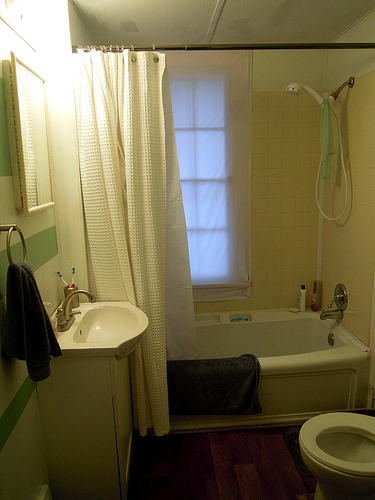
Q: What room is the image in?
A: It is at the bathroom.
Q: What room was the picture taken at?
A: It was taken at the bathroom.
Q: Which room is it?
A: It is a bathroom.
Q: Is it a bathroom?
A: Yes, it is a bathroom.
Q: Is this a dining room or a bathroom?
A: It is a bathroom.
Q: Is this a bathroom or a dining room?
A: It is a bathroom.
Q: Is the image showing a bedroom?
A: No, the picture is showing a bathroom.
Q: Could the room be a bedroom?
A: No, it is a bathroom.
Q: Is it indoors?
A: Yes, it is indoors.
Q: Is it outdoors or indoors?
A: It is indoors.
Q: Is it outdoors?
A: No, it is indoors.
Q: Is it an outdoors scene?
A: No, it is indoors.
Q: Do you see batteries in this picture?
A: No, there are no batteries.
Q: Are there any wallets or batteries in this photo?
A: No, there are no batteries or wallets.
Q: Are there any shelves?
A: No, there are no shelves.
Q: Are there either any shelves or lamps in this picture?
A: No, there are no shelves or lamps.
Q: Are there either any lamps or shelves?
A: No, there are no shelves or lamps.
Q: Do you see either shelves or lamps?
A: No, there are no shelves or lamps.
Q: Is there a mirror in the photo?
A: Yes, there is a mirror.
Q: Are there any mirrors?
A: Yes, there is a mirror.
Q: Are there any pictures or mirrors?
A: Yes, there is a mirror.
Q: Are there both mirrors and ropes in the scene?
A: No, there is a mirror but no ropes.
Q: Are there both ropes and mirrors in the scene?
A: No, there is a mirror but no ropes.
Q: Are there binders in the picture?
A: No, there are no binders.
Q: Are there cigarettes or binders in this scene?
A: No, there are no binders or cigarettes.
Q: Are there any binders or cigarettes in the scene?
A: No, there are no binders or cigarettes.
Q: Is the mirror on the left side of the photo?
A: Yes, the mirror is on the left of the image.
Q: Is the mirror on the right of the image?
A: No, the mirror is on the left of the image.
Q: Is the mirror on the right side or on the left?
A: The mirror is on the left of the image.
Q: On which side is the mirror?
A: The mirror is on the left of the image.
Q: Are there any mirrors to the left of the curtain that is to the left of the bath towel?
A: Yes, there is a mirror to the left of the curtain.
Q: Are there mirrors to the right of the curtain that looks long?
A: No, the mirror is to the left of the curtain.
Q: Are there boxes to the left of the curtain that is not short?
A: No, there is a mirror to the left of the curtain.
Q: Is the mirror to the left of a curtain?
A: Yes, the mirror is to the left of a curtain.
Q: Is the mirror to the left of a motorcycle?
A: No, the mirror is to the left of a curtain.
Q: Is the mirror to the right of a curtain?
A: No, the mirror is to the left of a curtain.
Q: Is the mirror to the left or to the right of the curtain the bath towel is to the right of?
A: The mirror is to the left of the curtain.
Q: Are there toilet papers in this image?
A: No, there are no toilet papers.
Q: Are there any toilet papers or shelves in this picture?
A: No, there are no toilet papers or shelves.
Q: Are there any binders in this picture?
A: No, there are no binders.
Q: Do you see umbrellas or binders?
A: No, there are no binders or umbrellas.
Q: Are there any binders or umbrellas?
A: No, there are no binders or umbrellas.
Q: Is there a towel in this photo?
A: Yes, there is a towel.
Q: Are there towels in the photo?
A: Yes, there is a towel.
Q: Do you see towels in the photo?
A: Yes, there is a towel.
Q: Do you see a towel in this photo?
A: Yes, there is a towel.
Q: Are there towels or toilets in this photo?
A: Yes, there is a towel.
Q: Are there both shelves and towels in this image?
A: No, there is a towel but no shelves.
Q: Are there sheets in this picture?
A: No, there are no sheets.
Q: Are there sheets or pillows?
A: No, there are no sheets or pillows.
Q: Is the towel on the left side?
A: Yes, the towel is on the left of the image.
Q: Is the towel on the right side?
A: No, the towel is on the left of the image.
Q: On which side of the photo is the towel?
A: The towel is on the left of the image.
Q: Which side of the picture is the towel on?
A: The towel is on the left of the image.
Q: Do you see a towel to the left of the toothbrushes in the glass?
A: Yes, there is a towel to the left of the toothbrushes.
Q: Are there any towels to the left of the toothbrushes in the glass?
A: Yes, there is a towel to the left of the toothbrushes.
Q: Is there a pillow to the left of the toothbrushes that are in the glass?
A: No, there is a towel to the left of the toothbrushes.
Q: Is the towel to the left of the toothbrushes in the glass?
A: Yes, the towel is to the left of the toothbrushes.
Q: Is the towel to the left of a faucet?
A: No, the towel is to the left of a curtain.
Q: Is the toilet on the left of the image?
A: No, the toilet is on the right of the image.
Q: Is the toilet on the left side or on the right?
A: The toilet is on the right of the image.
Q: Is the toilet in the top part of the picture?
A: No, the toilet is in the bottom of the image.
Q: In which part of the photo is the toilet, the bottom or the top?
A: The toilet is in the bottom of the image.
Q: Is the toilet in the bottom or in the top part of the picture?
A: The toilet is in the bottom of the image.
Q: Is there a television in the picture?
A: No, there are no televisions.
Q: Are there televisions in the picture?
A: No, there are no televisions.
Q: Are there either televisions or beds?
A: No, there are no televisions or beds.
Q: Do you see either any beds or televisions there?
A: No, there are no televisions or beds.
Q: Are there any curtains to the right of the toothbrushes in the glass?
A: Yes, there are curtains to the right of the toothbrushes.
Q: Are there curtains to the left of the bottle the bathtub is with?
A: Yes, there are curtains to the left of the bottle.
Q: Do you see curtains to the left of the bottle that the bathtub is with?
A: Yes, there are curtains to the left of the bottle.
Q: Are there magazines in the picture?
A: No, there are no magazines.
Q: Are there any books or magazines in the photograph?
A: No, there are no magazines or books.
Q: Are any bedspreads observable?
A: No, there are no bedspreads.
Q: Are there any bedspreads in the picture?
A: No, there are no bedspreads.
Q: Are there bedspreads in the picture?
A: No, there are no bedspreads.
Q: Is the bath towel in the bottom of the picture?
A: Yes, the bath towel is in the bottom of the image.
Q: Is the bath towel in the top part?
A: No, the bath towel is in the bottom of the image.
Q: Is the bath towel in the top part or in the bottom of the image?
A: The bath towel is in the bottom of the image.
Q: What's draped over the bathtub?
A: The bath towel is draped over the bathtub.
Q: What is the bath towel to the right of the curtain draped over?
A: The bath towel is draped over the tub.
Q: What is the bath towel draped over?
A: The bath towel is draped over the tub.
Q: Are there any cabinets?
A: Yes, there is a cabinet.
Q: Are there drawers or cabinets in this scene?
A: Yes, there is a cabinet.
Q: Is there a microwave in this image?
A: No, there are no microwaves.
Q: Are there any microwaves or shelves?
A: No, there are no microwaves or shelves.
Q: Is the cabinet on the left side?
A: Yes, the cabinet is on the left of the image.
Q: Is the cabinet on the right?
A: No, the cabinet is on the left of the image.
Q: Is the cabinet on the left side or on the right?
A: The cabinet is on the left of the image.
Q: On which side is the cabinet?
A: The cabinet is on the left of the image.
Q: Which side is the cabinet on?
A: The cabinet is on the left of the image.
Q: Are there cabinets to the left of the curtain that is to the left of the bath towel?
A: Yes, there is a cabinet to the left of the curtain.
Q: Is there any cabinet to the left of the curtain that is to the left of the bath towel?
A: Yes, there is a cabinet to the left of the curtain.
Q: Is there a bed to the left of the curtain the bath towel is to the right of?
A: No, there is a cabinet to the left of the curtain.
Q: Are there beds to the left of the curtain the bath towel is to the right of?
A: No, there is a cabinet to the left of the curtain.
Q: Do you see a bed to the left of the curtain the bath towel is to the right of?
A: No, there is a cabinet to the left of the curtain.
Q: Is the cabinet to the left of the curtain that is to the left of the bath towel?
A: Yes, the cabinet is to the left of the curtain.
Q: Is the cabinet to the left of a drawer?
A: No, the cabinet is to the left of the curtain.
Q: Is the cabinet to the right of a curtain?
A: No, the cabinet is to the left of a curtain.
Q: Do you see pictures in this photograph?
A: No, there are no pictures.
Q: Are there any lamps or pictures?
A: No, there are no pictures or lamps.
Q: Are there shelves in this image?
A: No, there are no shelves.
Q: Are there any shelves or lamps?
A: No, there are no shelves or lamps.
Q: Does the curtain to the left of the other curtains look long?
A: Yes, the curtain is long.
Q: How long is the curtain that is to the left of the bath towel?
A: The curtain is long.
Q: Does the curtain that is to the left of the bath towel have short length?
A: No, the curtain is long.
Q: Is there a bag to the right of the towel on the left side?
A: No, there is a curtain to the right of the towel.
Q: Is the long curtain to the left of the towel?
A: No, the curtain is to the right of the towel.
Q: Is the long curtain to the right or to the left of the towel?
A: The curtain is to the right of the towel.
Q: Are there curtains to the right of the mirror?
A: Yes, there is a curtain to the right of the mirror.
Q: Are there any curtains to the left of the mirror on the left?
A: No, the curtain is to the right of the mirror.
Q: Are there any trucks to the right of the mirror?
A: No, there is a curtain to the right of the mirror.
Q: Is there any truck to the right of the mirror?
A: No, there is a curtain to the right of the mirror.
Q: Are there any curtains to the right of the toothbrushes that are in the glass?
A: Yes, there is a curtain to the right of the toothbrushes.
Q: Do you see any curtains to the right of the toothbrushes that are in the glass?
A: Yes, there is a curtain to the right of the toothbrushes.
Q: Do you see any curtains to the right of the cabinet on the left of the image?
A: Yes, there is a curtain to the right of the cabinet.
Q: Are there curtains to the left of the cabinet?
A: No, the curtain is to the right of the cabinet.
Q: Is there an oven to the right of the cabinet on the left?
A: No, there is a curtain to the right of the cabinet.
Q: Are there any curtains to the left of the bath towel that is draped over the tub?
A: Yes, there is a curtain to the left of the bath towel.